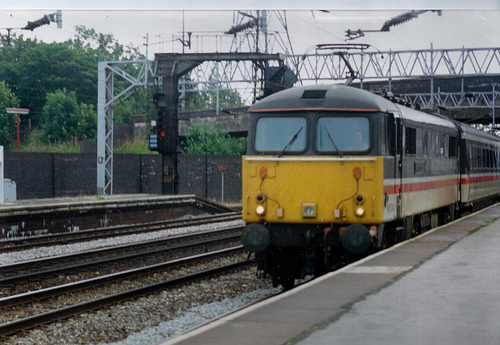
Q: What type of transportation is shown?
A: Train.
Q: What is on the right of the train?
A: Platform.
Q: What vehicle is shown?
A: Train.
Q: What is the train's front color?
A: Yellow.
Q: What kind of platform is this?
A: Train.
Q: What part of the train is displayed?
A: Front.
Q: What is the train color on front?
A: Yellow.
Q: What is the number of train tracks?
A: Four.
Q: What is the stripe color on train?
A: Red.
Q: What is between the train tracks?
A: Gravel.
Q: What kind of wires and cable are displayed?
A: Electrical.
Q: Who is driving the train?
A: A man.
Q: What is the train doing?
A: Pulling into the platform.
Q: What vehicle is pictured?
A: A train.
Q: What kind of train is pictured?
A: A passenger train.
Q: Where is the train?
A: At a station.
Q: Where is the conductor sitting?
A: On the right side of the cabin.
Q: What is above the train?
A: An electric power line.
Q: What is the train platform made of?
A: Cement.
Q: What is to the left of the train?
A: More train tracks.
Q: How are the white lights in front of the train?
A: Turned on.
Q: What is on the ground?
A: White lines.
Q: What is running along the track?
A: Brown fence.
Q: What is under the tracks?
A: Small rocks.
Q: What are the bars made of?
A: Steel.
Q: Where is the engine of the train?
A: Front of train.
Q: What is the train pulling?
A: A passenger car.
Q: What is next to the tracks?
A: A platform.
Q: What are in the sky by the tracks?
A: Steel towers.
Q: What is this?
A: Train.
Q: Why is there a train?
A: Travelling.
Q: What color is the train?
A: Yellow.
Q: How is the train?
A: In motion.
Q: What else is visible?
A: Train tracks.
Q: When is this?
A: Daytime.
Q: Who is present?
A: No one.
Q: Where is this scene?
A: Railroad.